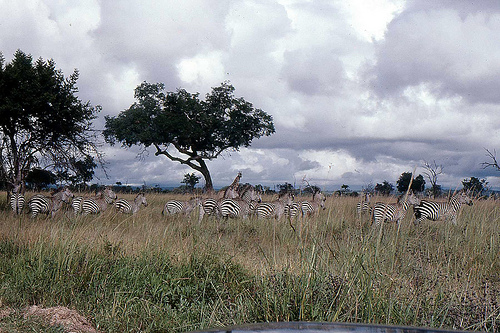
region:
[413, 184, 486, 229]
Zebra in a field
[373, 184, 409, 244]
Zebra in a field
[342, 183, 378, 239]
Zebra in a field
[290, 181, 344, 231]
Zebra in a field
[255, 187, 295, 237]
Zebra in a field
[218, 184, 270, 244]
Zebra in a field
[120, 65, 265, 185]
Tall green tree in a field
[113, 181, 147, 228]
Zebra in a field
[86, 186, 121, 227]
Zebra in a field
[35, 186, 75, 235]
Zebra in a field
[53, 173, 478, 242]
Zebras in the wilderness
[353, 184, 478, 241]
Zebras in the wilderness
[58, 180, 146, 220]
Zebras in the wilderness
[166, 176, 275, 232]
Zebras in the wilderness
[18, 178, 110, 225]
Zebras in the wilderness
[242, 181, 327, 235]
Zebras in the wilderness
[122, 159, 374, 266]
Zebras gathered in the field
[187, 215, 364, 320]
Medium length brown grass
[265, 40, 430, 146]
Sky full of clouds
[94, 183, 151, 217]
Zebra is striped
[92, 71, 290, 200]
Tree standing in the field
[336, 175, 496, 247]
Two adult zebras with baby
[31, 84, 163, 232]
Branches hanging down on tree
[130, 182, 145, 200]
Short mane on the zebra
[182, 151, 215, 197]
Trunk on tree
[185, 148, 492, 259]
Zebras looking in the distance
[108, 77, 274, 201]
tree in the plains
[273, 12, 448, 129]
cloudy sky in the distance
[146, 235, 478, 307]
tall grasses in the plains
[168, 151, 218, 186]
trunk of a tree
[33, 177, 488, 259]
zebras in the grasses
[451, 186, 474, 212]
head of a zebra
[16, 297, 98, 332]
rocks in the grass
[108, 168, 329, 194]
trees along the horizon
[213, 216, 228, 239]
back legs of a zebra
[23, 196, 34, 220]
tail of a zebra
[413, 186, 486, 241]
White and black zebra in field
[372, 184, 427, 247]
White and black zebra in field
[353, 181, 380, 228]
White and black zebra in field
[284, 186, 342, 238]
White and black zebra in field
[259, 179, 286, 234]
White and black zebra in field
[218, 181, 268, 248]
White and black zebra in field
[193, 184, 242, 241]
White and black zebra in field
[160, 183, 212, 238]
White and black zebra in field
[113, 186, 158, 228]
White and black zebra in field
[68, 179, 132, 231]
White and black zebra in field